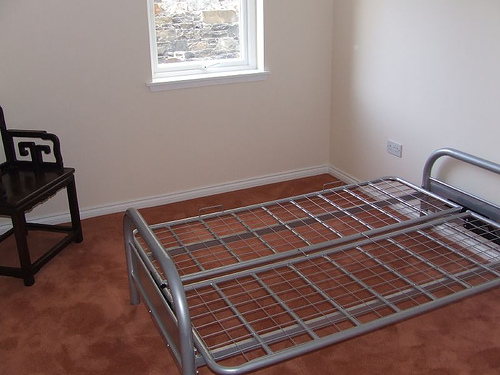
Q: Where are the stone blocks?
A: On the other side of the window.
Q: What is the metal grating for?
A: Bed mattress.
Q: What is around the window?
A: White frame.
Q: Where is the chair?
A: In the corner.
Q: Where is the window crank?
A: Center bottom of window frame.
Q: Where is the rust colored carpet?
A: On floor.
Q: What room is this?
A: Bedroom.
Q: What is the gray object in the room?
A: Bed Frame.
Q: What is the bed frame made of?
A: Metal.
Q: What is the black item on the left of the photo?
A: Chair.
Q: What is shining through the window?
A: Sunlight.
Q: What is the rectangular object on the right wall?
A: Outlet.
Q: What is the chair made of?
A: Wood.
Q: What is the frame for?
A: A bed.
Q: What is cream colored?
A: The wall.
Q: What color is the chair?
A: Black.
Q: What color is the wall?
A: White.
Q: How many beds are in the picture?
A: Zero.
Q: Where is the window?
A: The wall.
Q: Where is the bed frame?
A: The room.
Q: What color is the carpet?
A: Brown.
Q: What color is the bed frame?
A: Silver.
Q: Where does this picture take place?
A: A bedroom.